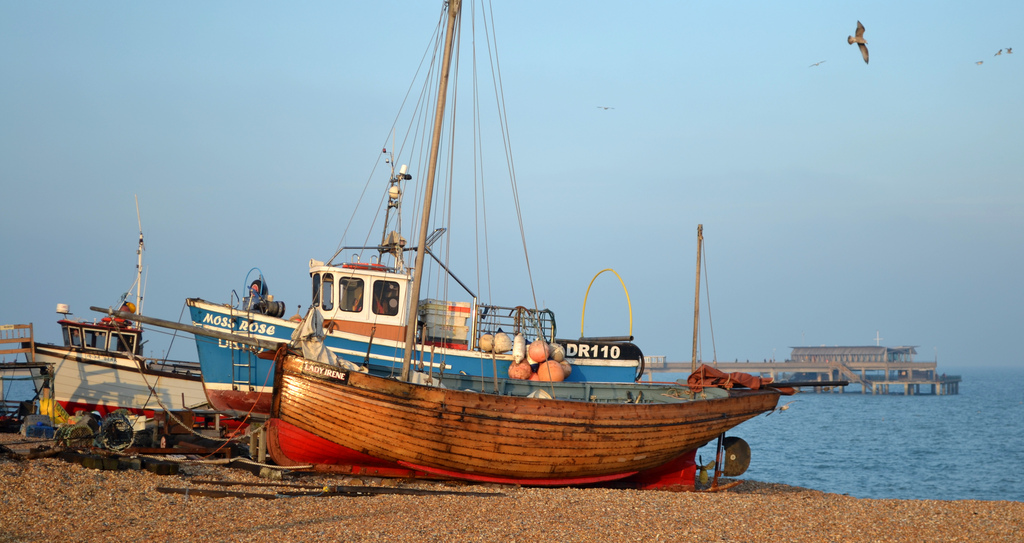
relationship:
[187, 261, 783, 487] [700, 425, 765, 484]
boat has rutter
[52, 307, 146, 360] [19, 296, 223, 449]
wheel house on fishing boat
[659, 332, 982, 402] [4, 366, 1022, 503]
pier into water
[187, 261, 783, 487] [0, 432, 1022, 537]
boat on shore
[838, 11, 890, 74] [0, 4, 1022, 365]
bird in sky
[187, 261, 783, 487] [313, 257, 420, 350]
boat has room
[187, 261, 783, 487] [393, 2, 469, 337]
boat has mast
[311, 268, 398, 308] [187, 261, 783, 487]
window on boat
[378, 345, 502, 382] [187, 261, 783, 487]
oar on boat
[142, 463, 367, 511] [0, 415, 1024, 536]
plank on beach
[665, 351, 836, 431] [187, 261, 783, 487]
cloth on boat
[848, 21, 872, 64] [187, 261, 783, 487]
bird above boat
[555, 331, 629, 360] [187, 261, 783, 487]
letters on boat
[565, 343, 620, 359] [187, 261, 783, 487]
letters on boat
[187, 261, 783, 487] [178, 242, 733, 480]
boat of boat